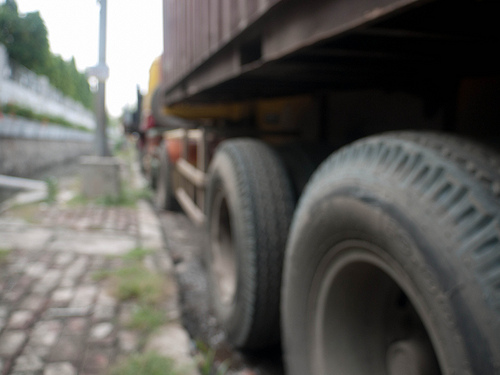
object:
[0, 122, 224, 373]
ground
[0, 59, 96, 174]
stone wall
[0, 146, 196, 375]
grass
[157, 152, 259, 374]
road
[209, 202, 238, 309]
hub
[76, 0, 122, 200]
flags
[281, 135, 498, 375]
tire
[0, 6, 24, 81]
trees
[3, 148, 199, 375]
walkway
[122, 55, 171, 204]
truck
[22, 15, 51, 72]
trees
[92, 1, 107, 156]
light pole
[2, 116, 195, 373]
cement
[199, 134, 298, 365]
tire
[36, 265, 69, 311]
cracks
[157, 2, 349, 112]
metal top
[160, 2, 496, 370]
truck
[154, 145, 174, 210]
tire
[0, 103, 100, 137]
greenery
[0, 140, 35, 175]
brick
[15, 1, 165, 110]
sky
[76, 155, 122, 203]
base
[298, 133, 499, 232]
tread